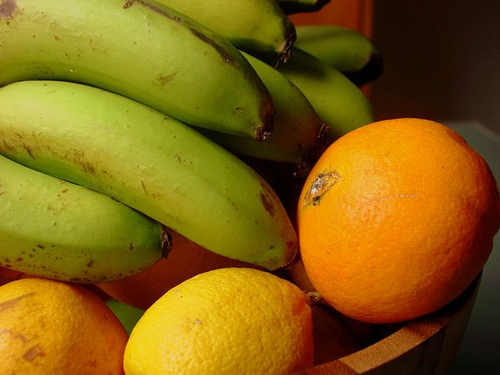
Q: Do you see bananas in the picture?
A: Yes, there is a banana.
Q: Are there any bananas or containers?
A: Yes, there is a banana.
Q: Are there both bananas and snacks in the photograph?
A: No, there is a banana but no snacks.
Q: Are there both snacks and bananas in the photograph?
A: No, there is a banana but no snacks.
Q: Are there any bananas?
A: Yes, there is a banana.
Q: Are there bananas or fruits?
A: Yes, there is a banana.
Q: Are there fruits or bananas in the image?
A: Yes, there is a banana.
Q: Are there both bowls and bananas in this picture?
A: Yes, there are both a banana and a bowl.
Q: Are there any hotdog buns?
A: No, there are no hotdog buns.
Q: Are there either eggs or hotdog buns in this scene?
A: No, there are no hotdog buns or eggs.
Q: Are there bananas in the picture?
A: Yes, there is a banana.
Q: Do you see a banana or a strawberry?
A: Yes, there is a banana.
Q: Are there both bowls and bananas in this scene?
A: Yes, there are both a banana and a bowl.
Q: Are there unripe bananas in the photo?
A: Yes, there is an unripe banana.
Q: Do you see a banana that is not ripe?
A: Yes, there is a unripe banana.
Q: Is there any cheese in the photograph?
A: No, there is no cheese.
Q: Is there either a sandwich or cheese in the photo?
A: No, there are no cheese or sandwiches.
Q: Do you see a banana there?
A: Yes, there is a banana.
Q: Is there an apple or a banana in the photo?
A: Yes, there is a banana.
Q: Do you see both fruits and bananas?
A: Yes, there are both a banana and a fruit.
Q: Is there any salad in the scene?
A: No, there is no salad.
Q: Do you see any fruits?
A: Yes, there is a fruit.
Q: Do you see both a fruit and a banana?
A: Yes, there are both a fruit and a banana.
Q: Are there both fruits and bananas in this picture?
A: Yes, there are both a fruit and bananas.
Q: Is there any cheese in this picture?
A: No, there is no cheese.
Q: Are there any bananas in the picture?
A: Yes, there is a banana.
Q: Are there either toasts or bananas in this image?
A: Yes, there is a banana.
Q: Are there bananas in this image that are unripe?
A: Yes, there is an unripe banana.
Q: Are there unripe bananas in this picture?
A: Yes, there is an unripe banana.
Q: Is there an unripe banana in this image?
A: Yes, there is an unripe banana.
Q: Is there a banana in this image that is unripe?
A: Yes, there is a banana that is unripe.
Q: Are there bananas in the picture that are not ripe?
A: Yes, there is a unripe banana.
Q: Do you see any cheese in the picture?
A: No, there is no cheese.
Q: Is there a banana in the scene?
A: Yes, there is a banana.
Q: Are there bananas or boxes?
A: Yes, there is a banana.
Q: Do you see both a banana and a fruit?
A: Yes, there are both a banana and a fruit.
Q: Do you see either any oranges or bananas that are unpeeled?
A: Yes, the banana is unpeeled.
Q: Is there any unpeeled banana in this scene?
A: Yes, there is an unpeeled banana.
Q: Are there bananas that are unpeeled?
A: Yes, there is a banana that is unpeeled.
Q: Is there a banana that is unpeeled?
A: Yes, there is a banana that is unpeeled.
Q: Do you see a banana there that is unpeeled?
A: Yes, there is a banana that is unpeeled.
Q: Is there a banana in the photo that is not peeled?
A: Yes, there is a unpeeled banana.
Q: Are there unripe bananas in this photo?
A: Yes, there is an unripe banana.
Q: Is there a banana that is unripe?
A: Yes, there is a banana that is unripe.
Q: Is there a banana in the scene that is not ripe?
A: Yes, there is a unripe banana.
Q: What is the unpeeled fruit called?
A: The fruit is a banana.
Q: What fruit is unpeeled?
A: The fruit is a banana.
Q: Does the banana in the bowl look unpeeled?
A: Yes, the banana is unpeeled.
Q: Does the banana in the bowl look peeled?
A: No, the banana is unpeeled.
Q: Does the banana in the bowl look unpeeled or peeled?
A: The banana is unpeeled.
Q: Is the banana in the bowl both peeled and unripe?
A: No, the banana is unripe but unpeeled.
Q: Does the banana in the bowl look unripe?
A: Yes, the banana is unripe.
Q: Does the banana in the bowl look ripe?
A: No, the banana is unripe.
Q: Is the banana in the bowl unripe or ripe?
A: The banana is unripe.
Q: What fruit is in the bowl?
A: The fruit is a banana.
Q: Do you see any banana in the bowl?
A: Yes, there is a banana in the bowl.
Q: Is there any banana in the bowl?
A: Yes, there is a banana in the bowl.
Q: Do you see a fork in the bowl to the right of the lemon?
A: No, there is a banana in the bowl.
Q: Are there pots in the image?
A: No, there are no pots.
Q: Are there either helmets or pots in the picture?
A: No, there are no pots or helmets.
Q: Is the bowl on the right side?
A: Yes, the bowl is on the right of the image.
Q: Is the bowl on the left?
A: No, the bowl is on the right of the image.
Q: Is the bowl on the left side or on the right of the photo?
A: The bowl is on the right of the image.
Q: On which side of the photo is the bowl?
A: The bowl is on the right of the image.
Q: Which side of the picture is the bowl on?
A: The bowl is on the right of the image.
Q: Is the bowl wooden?
A: Yes, the bowl is wooden.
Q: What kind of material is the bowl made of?
A: The bowl is made of wood.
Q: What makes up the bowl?
A: The bowl is made of wood.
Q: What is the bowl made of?
A: The bowl is made of wood.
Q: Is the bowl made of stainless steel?
A: No, the bowl is made of wood.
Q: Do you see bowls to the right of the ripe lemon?
A: Yes, there is a bowl to the right of the lemon.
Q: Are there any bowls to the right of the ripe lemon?
A: Yes, there is a bowl to the right of the lemon.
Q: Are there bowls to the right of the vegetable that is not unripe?
A: Yes, there is a bowl to the right of the lemon.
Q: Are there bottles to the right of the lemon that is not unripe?
A: No, there is a bowl to the right of the lemon.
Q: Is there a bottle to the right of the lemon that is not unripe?
A: No, there is a bowl to the right of the lemon.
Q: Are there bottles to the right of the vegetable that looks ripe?
A: No, there is a bowl to the right of the lemon.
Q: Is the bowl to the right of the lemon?
A: Yes, the bowl is to the right of the lemon.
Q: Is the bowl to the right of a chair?
A: No, the bowl is to the right of the lemon.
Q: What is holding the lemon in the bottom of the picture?
A: The bowl is holding the lemon.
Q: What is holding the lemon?
A: The bowl is holding the lemon.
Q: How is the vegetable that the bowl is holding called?
A: The vegetable is a lemon.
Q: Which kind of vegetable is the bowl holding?
A: The bowl is holding the lemon.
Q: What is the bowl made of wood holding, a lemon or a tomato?
A: The bowl is holding a lemon.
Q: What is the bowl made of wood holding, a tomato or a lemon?
A: The bowl is holding a lemon.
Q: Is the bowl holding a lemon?
A: Yes, the bowl is holding a lemon.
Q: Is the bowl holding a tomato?
A: No, the bowl is holding a lemon.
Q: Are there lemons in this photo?
A: Yes, there is a lemon.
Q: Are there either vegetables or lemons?
A: Yes, there is a lemon.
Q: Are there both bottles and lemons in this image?
A: No, there is a lemon but no bottles.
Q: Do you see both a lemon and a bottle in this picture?
A: No, there is a lemon but no bottles.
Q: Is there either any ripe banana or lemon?
A: Yes, there is a ripe lemon.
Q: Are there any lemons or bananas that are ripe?
A: Yes, the lemon is ripe.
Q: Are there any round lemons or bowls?
A: Yes, there is a round lemon.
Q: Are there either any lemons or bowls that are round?
A: Yes, the lemon is round.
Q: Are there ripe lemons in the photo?
A: Yes, there is a ripe lemon.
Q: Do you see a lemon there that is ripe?
A: Yes, there is a lemon that is ripe.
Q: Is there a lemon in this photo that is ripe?
A: Yes, there is a lemon that is ripe.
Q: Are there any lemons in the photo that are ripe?
A: Yes, there is a lemon that is ripe.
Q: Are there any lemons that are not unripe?
A: Yes, there is an ripe lemon.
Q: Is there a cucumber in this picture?
A: No, there are no cucumbers.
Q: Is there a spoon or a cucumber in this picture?
A: No, there are no cucumbers or spoons.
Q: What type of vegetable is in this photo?
A: The vegetable is a lemon.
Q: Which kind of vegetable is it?
A: The vegetable is a lemon.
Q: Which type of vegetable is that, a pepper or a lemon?
A: That is a lemon.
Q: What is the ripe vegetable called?
A: The vegetable is a lemon.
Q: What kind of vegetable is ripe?
A: The vegetable is a lemon.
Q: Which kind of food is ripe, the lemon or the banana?
A: The lemon is ripe.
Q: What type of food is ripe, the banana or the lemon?
A: The lemon is ripe.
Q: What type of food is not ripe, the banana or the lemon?
A: The banana is not ripe.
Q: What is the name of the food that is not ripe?
A: The food is a banana.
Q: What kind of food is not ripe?
A: The food is a banana.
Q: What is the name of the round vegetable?
A: The vegetable is a lemon.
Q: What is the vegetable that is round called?
A: The vegetable is a lemon.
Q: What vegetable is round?
A: The vegetable is a lemon.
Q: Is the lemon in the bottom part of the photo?
A: Yes, the lemon is in the bottom of the image.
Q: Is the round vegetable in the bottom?
A: Yes, the lemon is in the bottom of the image.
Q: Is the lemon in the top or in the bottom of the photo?
A: The lemon is in the bottom of the image.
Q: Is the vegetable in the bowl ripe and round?
A: Yes, the lemon is ripe and round.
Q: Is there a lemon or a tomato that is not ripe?
A: No, there is a lemon but it is ripe.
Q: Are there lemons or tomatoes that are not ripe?
A: No, there is a lemon but it is ripe.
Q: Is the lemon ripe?
A: Yes, the lemon is ripe.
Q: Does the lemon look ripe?
A: Yes, the lemon is ripe.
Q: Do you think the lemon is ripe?
A: Yes, the lemon is ripe.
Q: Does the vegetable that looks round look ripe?
A: Yes, the lemon is ripe.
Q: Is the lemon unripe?
A: No, the lemon is ripe.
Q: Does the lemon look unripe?
A: No, the lemon is ripe.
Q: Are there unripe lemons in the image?
A: No, there is a lemon but it is ripe.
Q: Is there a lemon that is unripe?
A: No, there is a lemon but it is ripe.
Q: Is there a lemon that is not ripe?
A: No, there is a lemon but it is ripe.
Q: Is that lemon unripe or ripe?
A: The lemon is ripe.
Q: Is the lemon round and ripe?
A: Yes, the lemon is round and ripe.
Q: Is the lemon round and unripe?
A: No, the lemon is round but ripe.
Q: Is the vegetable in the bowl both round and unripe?
A: No, the lemon is round but ripe.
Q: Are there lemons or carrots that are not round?
A: No, there is a lemon but it is round.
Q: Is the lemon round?
A: Yes, the lemon is round.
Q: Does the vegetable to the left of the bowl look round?
A: Yes, the lemon is round.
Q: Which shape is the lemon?
A: The lemon is round.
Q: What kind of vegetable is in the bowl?
A: The vegetable is a lemon.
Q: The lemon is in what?
A: The lemon is in the bowl.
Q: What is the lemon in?
A: The lemon is in the bowl.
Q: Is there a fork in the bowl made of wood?
A: No, there is a lemon in the bowl.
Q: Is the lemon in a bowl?
A: Yes, the lemon is in a bowl.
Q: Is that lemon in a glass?
A: No, the lemon is in a bowl.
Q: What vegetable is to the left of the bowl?
A: The vegetable is a lemon.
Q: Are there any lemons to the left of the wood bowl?
A: Yes, there is a lemon to the left of the bowl.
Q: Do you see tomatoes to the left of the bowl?
A: No, there is a lemon to the left of the bowl.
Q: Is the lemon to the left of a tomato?
A: No, the lemon is to the left of the bowl.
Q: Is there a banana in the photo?
A: Yes, there is a banana.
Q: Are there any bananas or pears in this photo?
A: Yes, there is a banana.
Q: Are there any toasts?
A: No, there are no toasts.